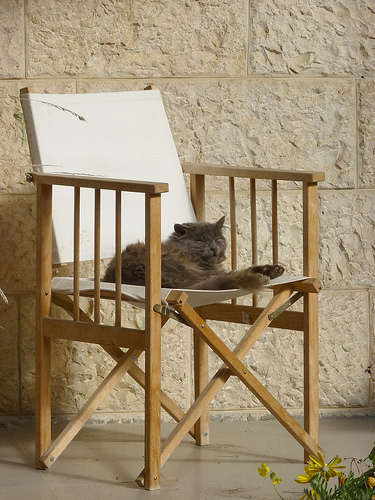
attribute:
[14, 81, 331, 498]
chair — wood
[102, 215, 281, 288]
cat — sleeping, lazy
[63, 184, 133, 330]
spindles — wood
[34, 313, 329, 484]
legs — wood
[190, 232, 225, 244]
eyes — closed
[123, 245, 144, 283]
fur — gray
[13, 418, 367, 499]
floor — concrete, gray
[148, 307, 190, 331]
hinge — steel